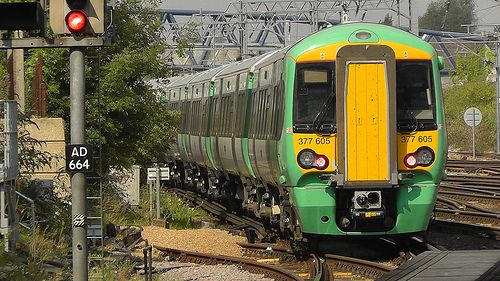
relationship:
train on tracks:
[126, 23, 451, 234] [163, 151, 499, 280]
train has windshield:
[126, 23, 451, 234] [294, 61, 436, 131]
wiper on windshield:
[308, 92, 334, 128] [294, 61, 436, 131]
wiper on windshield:
[394, 94, 419, 127] [294, 61, 436, 131]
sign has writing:
[63, 144, 89, 171] [67, 146, 89, 171]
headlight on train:
[315, 154, 325, 167] [126, 23, 451, 234]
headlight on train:
[407, 156, 416, 167] [126, 23, 451, 234]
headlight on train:
[298, 150, 314, 167] [126, 23, 451, 234]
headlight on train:
[419, 146, 434, 165] [126, 23, 451, 234]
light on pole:
[65, 10, 86, 32] [67, 50, 89, 281]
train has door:
[126, 23, 451, 234] [348, 63, 390, 182]